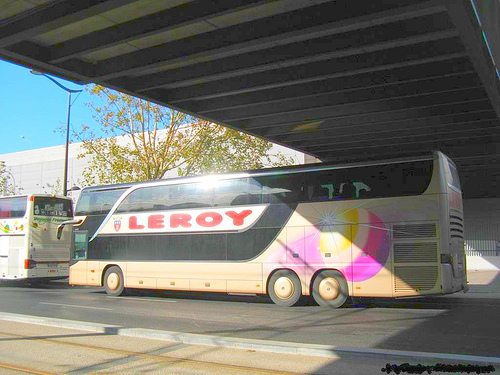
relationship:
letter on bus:
[141, 211, 166, 231] [68, 150, 470, 309]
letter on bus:
[170, 213, 193, 228] [68, 150, 470, 309]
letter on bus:
[166, 208, 193, 231] [68, 150, 470, 309]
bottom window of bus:
[125, 236, 155, 261] [68, 150, 470, 309]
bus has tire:
[68, 150, 470, 309] [311, 267, 352, 305]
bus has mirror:
[68, 150, 470, 309] [56, 223, 65, 240]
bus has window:
[68, 150, 470, 309] [384, 163, 449, 200]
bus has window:
[68, 150, 470, 309] [306, 167, 344, 190]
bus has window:
[68, 150, 470, 309] [214, 175, 256, 199]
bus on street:
[68, 150, 470, 309] [1, 280, 498, 358]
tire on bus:
[311, 267, 352, 308] [68, 150, 470, 309]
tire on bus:
[265, 268, 299, 309] [68, 150, 470, 309]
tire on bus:
[99, 264, 123, 296] [68, 150, 470, 309]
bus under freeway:
[68, 150, 470, 309] [5, 7, 495, 147]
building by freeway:
[13, 124, 219, 181] [4, 251, 498, 364]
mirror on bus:
[56, 220, 65, 240] [68, 150, 470, 309]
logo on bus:
[129, 209, 253, 229] [68, 150, 470, 309]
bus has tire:
[68, 150, 470, 309] [101, 264, 124, 296]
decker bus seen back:
[1, 193, 72, 285] [30, 195, 74, 279]